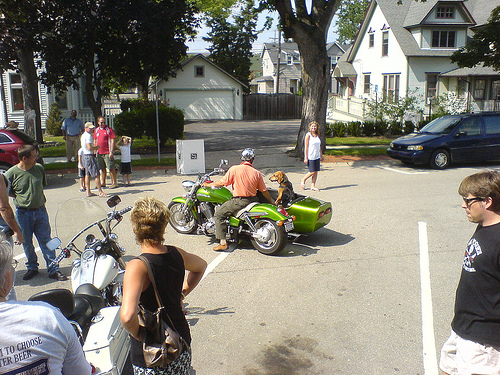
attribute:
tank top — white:
[304, 133, 326, 160]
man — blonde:
[439, 166, 499, 374]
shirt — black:
[447, 223, 499, 348]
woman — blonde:
[118, 202, 209, 371]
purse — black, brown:
[126, 254, 186, 367]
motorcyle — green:
[166, 161, 333, 255]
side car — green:
[259, 179, 333, 234]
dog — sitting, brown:
[270, 168, 297, 206]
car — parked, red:
[0, 123, 45, 182]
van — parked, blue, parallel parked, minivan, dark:
[382, 94, 500, 168]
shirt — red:
[95, 127, 113, 154]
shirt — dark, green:
[4, 165, 52, 209]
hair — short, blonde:
[132, 197, 171, 246]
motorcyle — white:
[46, 195, 138, 372]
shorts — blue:
[307, 155, 324, 172]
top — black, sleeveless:
[127, 244, 187, 367]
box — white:
[170, 132, 216, 183]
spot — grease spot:
[239, 320, 342, 372]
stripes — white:
[189, 208, 445, 374]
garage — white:
[150, 45, 251, 123]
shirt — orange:
[220, 161, 266, 201]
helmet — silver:
[239, 146, 258, 162]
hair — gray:
[1, 237, 14, 277]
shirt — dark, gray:
[2, 299, 94, 374]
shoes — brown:
[215, 239, 231, 254]